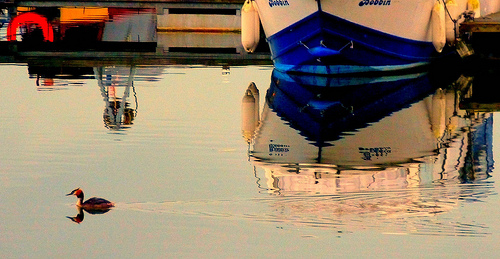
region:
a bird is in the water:
[50, 176, 137, 218]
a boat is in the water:
[231, 8, 471, 135]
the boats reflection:
[231, 51, 486, 195]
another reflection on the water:
[30, 50, 175, 130]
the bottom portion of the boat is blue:
[270, 20, 435, 84]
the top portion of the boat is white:
[239, 2, 464, 22]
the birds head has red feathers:
[72, 187, 84, 194]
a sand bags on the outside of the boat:
[238, 1, 262, 55]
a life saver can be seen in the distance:
[1, 6, 61, 53]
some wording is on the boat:
[259, 0, 405, 15]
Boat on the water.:
[217, 1, 480, 81]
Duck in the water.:
[62, 183, 114, 218]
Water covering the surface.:
[2, 50, 499, 257]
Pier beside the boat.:
[454, 13, 496, 63]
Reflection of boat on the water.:
[232, 67, 497, 200]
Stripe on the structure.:
[153, 23, 244, 38]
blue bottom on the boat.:
[256, 10, 441, 78]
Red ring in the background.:
[5, 10, 56, 42]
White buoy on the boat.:
[233, 0, 263, 55]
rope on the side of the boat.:
[438, 0, 468, 41]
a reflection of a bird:
[51, 182, 122, 224]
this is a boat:
[252, 5, 460, 60]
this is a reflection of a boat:
[268, 83, 413, 168]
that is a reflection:
[98, 72, 142, 133]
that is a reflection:
[32, 58, 64, 105]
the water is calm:
[210, 196, 291, 246]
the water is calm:
[155, 93, 180, 217]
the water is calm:
[14, 175, 56, 227]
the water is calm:
[21, 112, 59, 149]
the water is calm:
[281, 201, 349, 231]